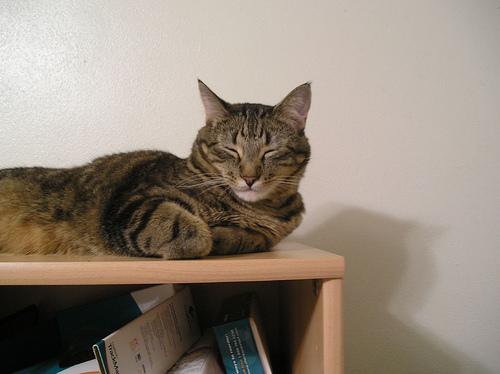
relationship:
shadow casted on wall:
[288, 203, 492, 373] [6, 8, 492, 371]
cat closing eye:
[2, 76, 315, 260] [217, 141, 240, 157]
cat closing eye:
[2, 76, 315, 260] [258, 143, 278, 159]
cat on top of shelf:
[0, 76, 312, 260] [3, 244, 334, 286]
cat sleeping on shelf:
[0, 76, 312, 260] [3, 244, 334, 286]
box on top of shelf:
[218, 309, 273, 372] [6, 280, 346, 370]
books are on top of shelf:
[18, 296, 292, 369] [5, 259, 340, 365]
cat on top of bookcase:
[0, 76, 312, 260] [4, 252, 347, 371]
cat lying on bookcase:
[0, 76, 312, 260] [4, 252, 347, 371]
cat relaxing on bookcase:
[2, 76, 315, 260] [4, 252, 347, 371]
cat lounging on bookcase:
[2, 76, 315, 260] [4, 252, 347, 371]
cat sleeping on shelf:
[2, 76, 315, 260] [5, 259, 340, 365]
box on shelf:
[211, 289, 276, 374] [5, 259, 340, 365]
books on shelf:
[92, 285, 203, 374] [4, 245, 345, 368]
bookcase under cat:
[0, 239, 347, 373] [2, 76, 315, 260]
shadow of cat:
[295, 191, 493, 371] [2, 76, 315, 260]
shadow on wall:
[295, 191, 493, 371] [6, 8, 492, 371]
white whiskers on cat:
[191, 167, 291, 190] [2, 76, 315, 260]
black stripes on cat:
[112, 79, 319, 254] [2, 76, 315, 260]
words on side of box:
[220, 324, 250, 371] [211, 289, 276, 374]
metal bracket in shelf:
[300, 273, 324, 310] [3, 254, 349, 370]